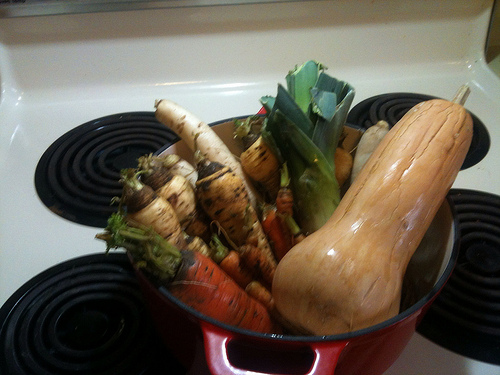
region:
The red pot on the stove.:
[122, 118, 452, 373]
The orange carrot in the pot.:
[164, 251, 273, 328]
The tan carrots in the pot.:
[150, 160, 278, 306]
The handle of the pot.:
[204, 328, 342, 373]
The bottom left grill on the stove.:
[15, 268, 177, 373]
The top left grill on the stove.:
[41, 127, 179, 212]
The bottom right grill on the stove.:
[450, 192, 499, 339]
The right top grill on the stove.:
[363, 87, 481, 167]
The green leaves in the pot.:
[273, 42, 340, 216]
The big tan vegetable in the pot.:
[274, 93, 499, 353]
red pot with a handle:
[197, 328, 400, 373]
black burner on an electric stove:
[15, 264, 144, 366]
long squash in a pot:
[274, 95, 469, 333]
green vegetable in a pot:
[279, 65, 339, 230]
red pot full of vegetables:
[111, 64, 445, 346]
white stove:
[21, 17, 461, 61]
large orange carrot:
[171, 245, 271, 328]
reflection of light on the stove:
[151, 76, 265, 91]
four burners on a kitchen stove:
[7, 95, 496, 371]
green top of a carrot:
[103, 217, 178, 282]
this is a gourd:
[263, 80, 481, 346]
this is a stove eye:
[21, 88, 208, 238]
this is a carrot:
[111, 213, 295, 348]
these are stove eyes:
[4, 75, 497, 369]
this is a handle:
[191, 299, 357, 373]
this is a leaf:
[268, 120, 336, 194]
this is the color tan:
[341, 191, 366, 228]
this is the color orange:
[188, 290, 208, 303]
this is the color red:
[373, 351, 385, 361]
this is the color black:
[463, 318, 493, 350]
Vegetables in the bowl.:
[67, 51, 418, 368]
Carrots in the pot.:
[85, 50, 333, 345]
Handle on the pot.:
[195, 312, 370, 371]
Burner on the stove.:
[15, 78, 246, 260]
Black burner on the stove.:
[35, 87, 258, 253]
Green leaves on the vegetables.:
[245, 45, 385, 245]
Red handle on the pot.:
[181, 313, 351, 373]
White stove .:
[9, 11, 325, 158]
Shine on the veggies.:
[328, 183, 424, 314]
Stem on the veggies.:
[432, 70, 474, 116]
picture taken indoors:
[16, 6, 492, 372]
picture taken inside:
[20, 11, 498, 349]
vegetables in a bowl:
[93, 65, 495, 345]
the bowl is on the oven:
[85, 60, 482, 357]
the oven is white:
[66, 25, 348, 76]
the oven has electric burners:
[45, 101, 227, 369]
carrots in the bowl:
[132, 145, 267, 303]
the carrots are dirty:
[115, 80, 282, 314]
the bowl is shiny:
[175, 307, 307, 372]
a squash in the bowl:
[260, 28, 488, 338]